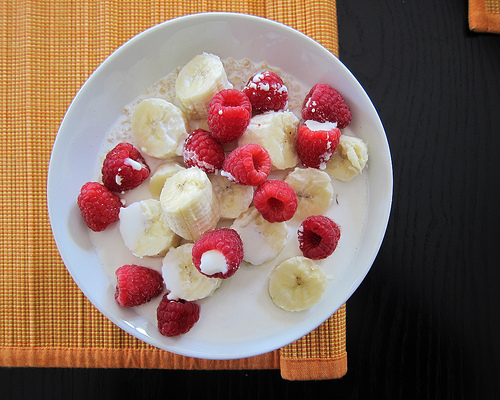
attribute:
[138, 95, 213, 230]
bananas — yellow, white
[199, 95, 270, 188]
berry — red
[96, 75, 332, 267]
milk — white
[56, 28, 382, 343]
bowl — white, round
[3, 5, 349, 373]
table — brown, orange